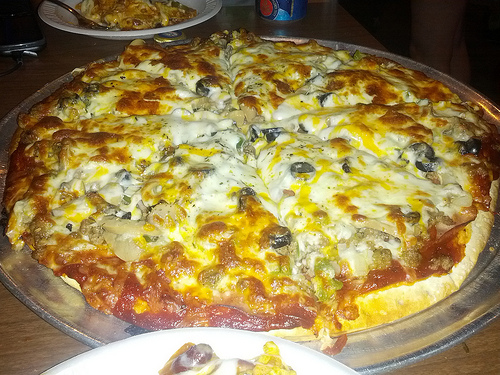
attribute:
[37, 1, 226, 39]
plate — white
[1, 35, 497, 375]
tray — silver, large, round, metal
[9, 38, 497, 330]
pizza — big, delicious, very cheesy, deep dish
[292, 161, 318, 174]
olive — black, topping, sliced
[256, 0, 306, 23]
can — blue, beverage, soda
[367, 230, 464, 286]
sauce — red, tomato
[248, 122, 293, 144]
olives — black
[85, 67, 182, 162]
cheese — cheddar, burnt, orange, white, melted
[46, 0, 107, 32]
fork — silver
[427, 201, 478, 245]
sausage — cooked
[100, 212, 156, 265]
mushroom — beige, large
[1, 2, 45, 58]
phone — charging, black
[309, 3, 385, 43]
table — wooden